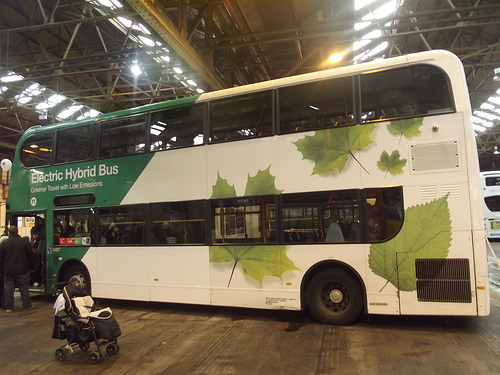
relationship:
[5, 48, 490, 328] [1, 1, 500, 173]
bus under structure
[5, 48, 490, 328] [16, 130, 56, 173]
bus has window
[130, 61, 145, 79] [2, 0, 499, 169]
light on ceiling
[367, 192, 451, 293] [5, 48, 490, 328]
leaf on bus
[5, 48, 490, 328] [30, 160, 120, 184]
bus has decal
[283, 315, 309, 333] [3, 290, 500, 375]
fluid on concrete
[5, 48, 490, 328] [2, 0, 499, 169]
bus under ceiling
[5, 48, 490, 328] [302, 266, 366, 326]
bus has wheel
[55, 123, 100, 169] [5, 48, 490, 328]
window on bus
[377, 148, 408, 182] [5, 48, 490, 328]
leaf on bus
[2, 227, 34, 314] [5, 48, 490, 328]
man beside bus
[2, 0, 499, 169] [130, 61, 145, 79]
ceiling has light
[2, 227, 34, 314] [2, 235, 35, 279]
man wearing black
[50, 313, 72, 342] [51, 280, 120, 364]
bags on stroller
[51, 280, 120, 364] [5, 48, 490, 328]
stroller next to bus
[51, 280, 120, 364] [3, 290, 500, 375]
stroller on floor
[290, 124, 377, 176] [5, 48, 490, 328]
leaf on bus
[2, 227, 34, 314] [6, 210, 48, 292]
man beside door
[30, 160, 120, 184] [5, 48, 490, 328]
decal on bus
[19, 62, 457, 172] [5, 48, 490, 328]
windows on bus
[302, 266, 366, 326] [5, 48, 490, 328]
tire on bus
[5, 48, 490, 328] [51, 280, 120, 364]
bus next to stroller